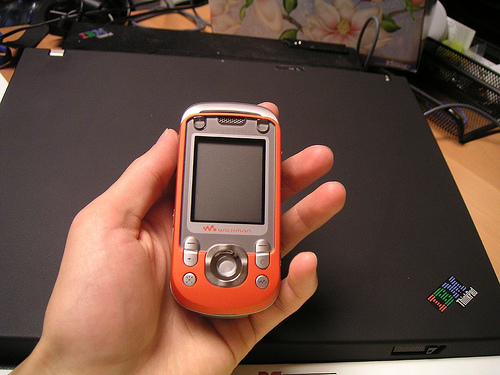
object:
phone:
[166, 99, 283, 319]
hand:
[0, 100, 350, 375]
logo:
[425, 274, 480, 315]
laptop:
[0, 44, 500, 369]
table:
[0, 0, 500, 284]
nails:
[155, 127, 170, 143]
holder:
[367, 34, 499, 146]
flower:
[297, 2, 393, 52]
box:
[210, 1, 437, 74]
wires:
[131, 6, 207, 31]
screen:
[189, 134, 267, 226]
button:
[204, 242, 248, 287]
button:
[181, 236, 199, 267]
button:
[254, 238, 271, 271]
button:
[182, 272, 197, 288]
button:
[255, 274, 270, 291]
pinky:
[254, 250, 320, 343]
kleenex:
[384, 59, 410, 72]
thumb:
[62, 128, 180, 244]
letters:
[454, 286, 480, 309]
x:
[184, 275, 194, 285]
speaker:
[217, 117, 247, 126]